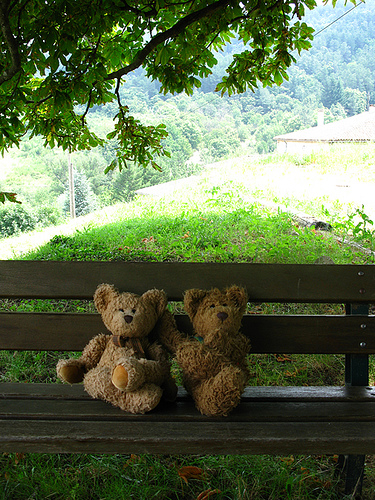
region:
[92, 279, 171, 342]
the head of a teddy bear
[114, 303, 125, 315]
the eye of a teddy bear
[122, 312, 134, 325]
the nose of a teddy bear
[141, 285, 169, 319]
the ear of a teddy bear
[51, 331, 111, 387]
the arm of a teddy bear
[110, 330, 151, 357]
a ribbon on the teddy bear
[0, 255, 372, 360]
the back of a bench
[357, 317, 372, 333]
a bolt on the bench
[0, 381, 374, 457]
the seat of the bench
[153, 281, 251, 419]
a brown teddy bear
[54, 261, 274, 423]
Two stuffed bears on a bench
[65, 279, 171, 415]
A stuffed bear with legs crossed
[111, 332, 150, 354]
A dark brown tie on a bear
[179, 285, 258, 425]
A dark brown stuffed bear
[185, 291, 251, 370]
Bear's arms covering his mouth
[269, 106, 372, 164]
A stone building with the light shining on it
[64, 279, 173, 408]
A light brown stuffed bear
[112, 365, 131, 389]
A circular portion of bear's foot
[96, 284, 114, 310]
A bear's ear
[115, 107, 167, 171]
The leaves of the tree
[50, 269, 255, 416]
two teddy bears sitting on bench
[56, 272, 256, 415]
teddy bears with their legs crossed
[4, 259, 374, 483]
brown bench bears are sitting on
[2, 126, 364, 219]
sunlight shining on grass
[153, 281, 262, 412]
bear putting arm around other bear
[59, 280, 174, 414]
bear wearing bowtie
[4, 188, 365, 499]
grass brown bench is on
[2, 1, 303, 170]
tree limb hanging over bench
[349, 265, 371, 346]
bolts holding back to bench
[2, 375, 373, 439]
three plank seat of bench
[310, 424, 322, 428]
part of a bench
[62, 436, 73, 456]
edge of a bench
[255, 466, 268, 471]
part of a lawn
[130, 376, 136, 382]
part of a doll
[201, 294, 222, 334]
face of a doll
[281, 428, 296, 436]
edge of a bench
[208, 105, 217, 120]
part of a forest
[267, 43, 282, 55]
part of a twig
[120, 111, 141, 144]
part of a branch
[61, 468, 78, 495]
part of a field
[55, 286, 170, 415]
Teddy bear with his legs crossed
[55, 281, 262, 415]
Two teddy bears sitting on the bench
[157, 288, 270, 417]
Teddy bear with his hand under chin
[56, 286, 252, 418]
Brown teddy bear kicking the other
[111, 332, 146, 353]
Teddy bear wearing a brown bowtie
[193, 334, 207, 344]
Part of a green bow tie on teddy bear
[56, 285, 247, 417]
Right teddy bear is darker than the other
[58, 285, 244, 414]
Teddy bears sitting in a garden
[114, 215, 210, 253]
Grass with pink and orange flowers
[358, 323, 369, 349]
Metal bolts in the bench